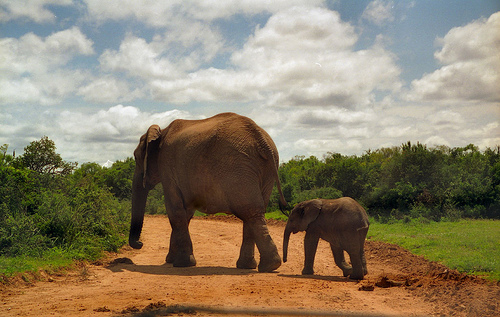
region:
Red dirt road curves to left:
[2, 200, 499, 313]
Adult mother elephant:
[125, 110, 290, 274]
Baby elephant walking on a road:
[277, 195, 372, 280]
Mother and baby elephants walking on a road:
[124, 105, 376, 288]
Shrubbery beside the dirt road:
[1, 138, 130, 255]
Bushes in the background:
[99, 140, 496, 219]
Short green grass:
[256, 200, 498, 287]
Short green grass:
[0, 253, 80, 281]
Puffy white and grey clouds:
[2, 0, 498, 163]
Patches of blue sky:
[2, 2, 499, 119]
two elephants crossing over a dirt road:
[120, 105, 382, 282]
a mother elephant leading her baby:
[123, 110, 286, 275]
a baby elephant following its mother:
[281, 195, 375, 285]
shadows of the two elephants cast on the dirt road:
[103, 253, 365, 285]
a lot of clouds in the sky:
[1, 0, 499, 154]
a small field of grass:
[373, 219, 499, 277]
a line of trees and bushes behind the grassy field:
[280, 137, 499, 221]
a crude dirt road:
[0, 210, 499, 315]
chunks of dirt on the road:
[351, 268, 421, 295]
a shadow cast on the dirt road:
[128, 295, 377, 315]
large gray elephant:
[114, 108, 277, 258]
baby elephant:
[287, 194, 378, 277]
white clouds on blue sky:
[21, 18, 79, 60]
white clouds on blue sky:
[1, 56, 77, 94]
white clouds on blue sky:
[21, 91, 113, 127]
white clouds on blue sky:
[83, 23, 140, 65]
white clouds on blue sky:
[67, 70, 135, 122]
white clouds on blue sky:
[143, 15, 196, 53]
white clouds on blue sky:
[154, 37, 224, 89]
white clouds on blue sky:
[239, 30, 345, 90]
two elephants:
[112, 104, 372, 273]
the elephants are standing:
[126, 114, 377, 285]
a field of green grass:
[427, 215, 499, 255]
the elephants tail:
[262, 141, 294, 216]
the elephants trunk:
[279, 226, 296, 261]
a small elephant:
[285, 203, 372, 278]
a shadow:
[129, 252, 169, 283]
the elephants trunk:
[125, 171, 153, 254]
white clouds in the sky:
[225, 7, 382, 107]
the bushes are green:
[359, 148, 471, 205]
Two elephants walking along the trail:
[119, 104, 378, 314]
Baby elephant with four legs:
[280, 196, 394, 292]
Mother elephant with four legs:
[119, 97, 285, 274]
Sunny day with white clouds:
[262, 23, 407, 122]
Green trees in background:
[387, 138, 494, 220]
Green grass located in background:
[431, 217, 496, 264]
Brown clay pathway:
[113, 266, 202, 312]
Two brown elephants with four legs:
[129, 107, 380, 288]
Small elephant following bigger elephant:
[126, 114, 376, 289]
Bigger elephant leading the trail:
[105, 103, 370, 298]